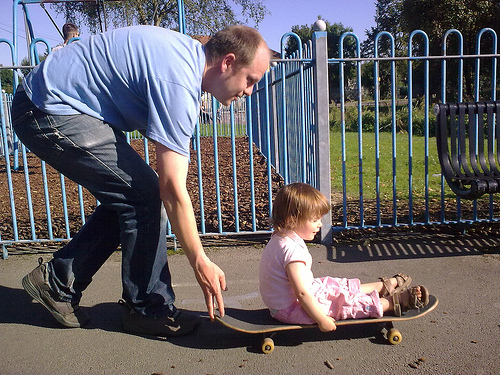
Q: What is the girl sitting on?
A: A skateboard.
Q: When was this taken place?
A: In the daytime.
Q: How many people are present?
A: Two.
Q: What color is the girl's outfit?
A: Pink.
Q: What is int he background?
A: A fence.